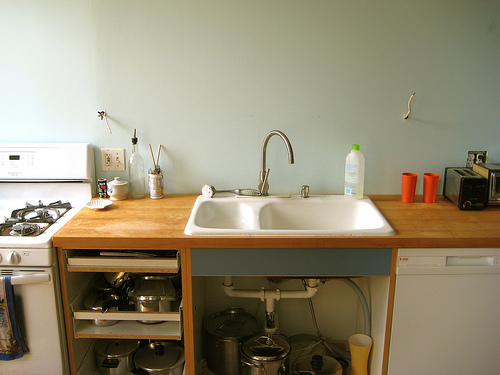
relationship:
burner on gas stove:
[11, 194, 78, 222] [2, 133, 95, 373]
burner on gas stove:
[0, 214, 55, 242] [2, 133, 95, 373]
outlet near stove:
[101, 148, 125, 172] [1, 197, 71, 238]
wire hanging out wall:
[389, 87, 442, 146] [5, 2, 498, 199]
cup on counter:
[423, 173, 439, 204] [380, 189, 480, 281]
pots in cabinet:
[78, 270, 181, 328] [61, 247, 387, 373]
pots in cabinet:
[237, 336, 290, 375] [61, 247, 387, 373]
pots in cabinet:
[200, 300, 265, 372] [61, 247, 387, 373]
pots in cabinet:
[288, 351, 344, 373] [61, 247, 387, 373]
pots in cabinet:
[130, 339, 182, 373] [61, 247, 387, 373]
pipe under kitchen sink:
[221, 276, 317, 334] [183, 194, 395, 237]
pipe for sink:
[220, 276, 321, 341] [184, 188, 394, 237]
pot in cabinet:
[91, 339, 134, 374] [62, 240, 194, 370]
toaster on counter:
[442, 166, 492, 211] [50, 192, 497, 245]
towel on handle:
[0, 273, 25, 360] [10, 274, 50, 283]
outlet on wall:
[101, 148, 125, 172] [5, 2, 498, 199]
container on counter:
[148, 168, 167, 199] [111, 183, 188, 258]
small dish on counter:
[87, 194, 125, 216] [77, 202, 221, 240]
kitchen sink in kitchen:
[183, 194, 395, 237] [6, 1, 496, 371]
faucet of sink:
[260, 125, 292, 190] [184, 188, 394, 237]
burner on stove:
[4, 220, 46, 238] [1, 116, 73, 251]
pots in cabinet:
[78, 270, 184, 373] [55, 247, 188, 373]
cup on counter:
[402, 172, 418, 202] [379, 197, 489, 247]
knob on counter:
[4, 245, 22, 271] [0, 196, 102, 265]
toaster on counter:
[445, 164, 487, 211] [50, 192, 497, 245]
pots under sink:
[200, 300, 265, 372] [182, 184, 398, 239]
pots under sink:
[235, 328, 291, 373] [182, 184, 398, 239]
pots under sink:
[285, 349, 342, 370] [182, 184, 398, 239]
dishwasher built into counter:
[389, 250, 495, 372] [381, 183, 498, 251]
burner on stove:
[7, 197, 76, 222] [0, 199, 72, 251]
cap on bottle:
[348, 140, 361, 150] [340, 144, 369, 204]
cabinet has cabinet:
[53, 231, 194, 371] [55, 238, 193, 375]